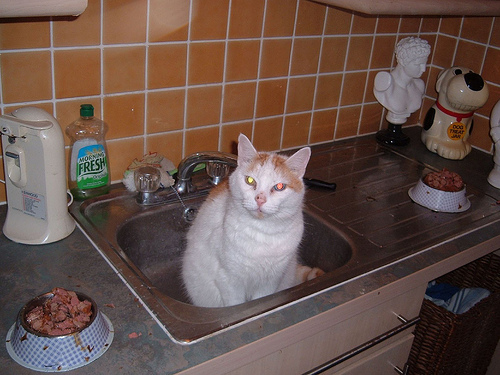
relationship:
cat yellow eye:
[160, 124, 343, 314] [245, 175, 257, 187]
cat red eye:
[160, 124, 343, 314] [272, 181, 286, 192]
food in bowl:
[22, 287, 96, 334] [5, 287, 119, 371]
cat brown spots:
[160, 124, 343, 314] [205, 146, 307, 208]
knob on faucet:
[131, 165, 164, 199] [172, 137, 343, 208]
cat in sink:
[160, 124, 343, 314] [114, 178, 357, 312]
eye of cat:
[267, 175, 289, 198] [160, 124, 343, 314]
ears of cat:
[229, 125, 311, 176] [160, 124, 343, 314]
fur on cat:
[191, 182, 308, 304] [160, 124, 343, 314]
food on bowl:
[22, 287, 96, 334] [5, 287, 119, 371]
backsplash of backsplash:
[0, 0, 498, 207] [2, 4, 498, 170]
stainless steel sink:
[73, 134, 492, 337] [114, 178, 357, 312]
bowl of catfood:
[5, 287, 119, 371] [22, 287, 96, 334]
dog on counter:
[420, 65, 489, 158] [16, 114, 492, 347]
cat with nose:
[160, 124, 343, 314] [253, 191, 268, 207]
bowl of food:
[5, 287, 119, 371] [22, 287, 96, 334]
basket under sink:
[411, 255, 494, 373] [114, 178, 357, 312]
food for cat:
[22, 287, 96, 334] [160, 124, 343, 314]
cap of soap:
[79, 105, 96, 118] [56, 102, 116, 201]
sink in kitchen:
[114, 178, 357, 312] [3, 4, 490, 368]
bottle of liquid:
[56, 102, 116, 201] [71, 185, 112, 200]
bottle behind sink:
[56, 102, 116, 201] [96, 180, 379, 322]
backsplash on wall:
[0, 0, 498, 207] [8, 10, 498, 206]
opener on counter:
[4, 100, 74, 241] [4, 204, 187, 371]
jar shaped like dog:
[419, 62, 491, 160] [420, 65, 489, 158]